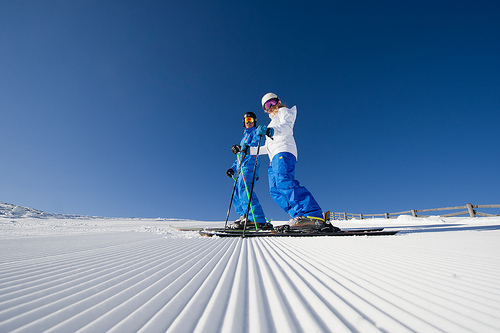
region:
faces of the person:
[218, 84, 300, 134]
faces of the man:
[226, 83, 299, 125]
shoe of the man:
[224, 186, 283, 246]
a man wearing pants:
[258, 147, 325, 222]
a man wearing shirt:
[260, 113, 306, 158]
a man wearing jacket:
[256, 103, 308, 166]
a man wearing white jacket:
[249, 92, 296, 162]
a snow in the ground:
[132, 216, 362, 326]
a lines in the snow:
[100, 238, 360, 332]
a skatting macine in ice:
[188, 200, 395, 245]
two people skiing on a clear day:
[179, 46, 412, 301]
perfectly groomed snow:
[95, 250, 226, 313]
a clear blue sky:
[315, 47, 415, 153]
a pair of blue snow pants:
[262, 157, 339, 232]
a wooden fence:
[401, 189, 484, 226]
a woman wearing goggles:
[252, 90, 284, 115]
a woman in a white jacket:
[253, 106, 319, 156]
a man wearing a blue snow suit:
[222, 119, 271, 230]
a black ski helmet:
[234, 110, 261, 135]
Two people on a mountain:
[157, 55, 404, 242]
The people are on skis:
[167, 80, 372, 244]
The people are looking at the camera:
[192, 78, 397, 253]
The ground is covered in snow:
[13, 229, 476, 329]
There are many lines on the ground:
[6, 227, 317, 322]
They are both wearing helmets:
[225, 90, 292, 127]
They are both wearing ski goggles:
[222, 73, 292, 128]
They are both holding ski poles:
[215, 119, 275, 232]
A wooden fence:
[330, 195, 484, 220]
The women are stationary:
[202, 90, 392, 240]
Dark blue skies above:
[23, 9, 220, 117]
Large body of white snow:
[12, 222, 166, 331]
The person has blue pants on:
[263, 148, 330, 215]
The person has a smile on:
[253, 88, 313, 170]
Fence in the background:
[347, 202, 491, 219]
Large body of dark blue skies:
[3, 3, 211, 193]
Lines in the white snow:
[28, 248, 318, 322]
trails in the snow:
[107, 238, 357, 326]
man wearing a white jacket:
[258, 109, 306, 156]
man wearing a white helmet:
[257, 89, 277, 102]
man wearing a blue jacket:
[226, 128, 265, 172]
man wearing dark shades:
[243, 113, 263, 128]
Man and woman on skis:
[179, 102, 384, 243]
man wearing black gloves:
[208, 134, 242, 183]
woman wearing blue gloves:
[249, 119, 268, 148]